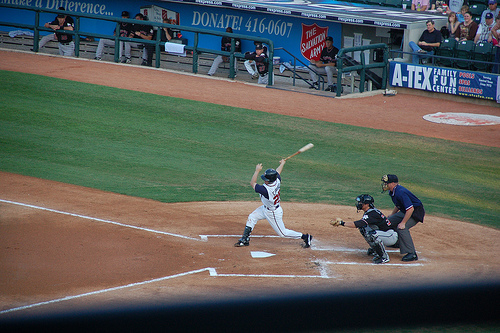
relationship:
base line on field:
[2, 195, 195, 248] [3, 43, 499, 316]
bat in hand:
[279, 140, 312, 161] [281, 161, 288, 165]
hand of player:
[281, 161, 288, 165] [242, 159, 312, 256]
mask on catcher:
[354, 195, 363, 214] [331, 192, 394, 265]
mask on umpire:
[381, 174, 391, 193] [383, 175, 432, 261]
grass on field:
[1, 71, 499, 231] [3, 43, 499, 316]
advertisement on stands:
[390, 63, 495, 99] [2, 1, 499, 114]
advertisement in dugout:
[1, 1, 344, 69] [0, 2, 392, 100]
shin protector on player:
[242, 218, 254, 241] [242, 159, 312, 256]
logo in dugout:
[299, 19, 333, 63] [0, 2, 392, 100]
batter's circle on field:
[422, 104, 499, 137] [3, 43, 499, 316]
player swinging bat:
[242, 159, 312, 256] [279, 140, 312, 161]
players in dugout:
[37, 9, 337, 86] [0, 2, 392, 100]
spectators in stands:
[399, 3, 497, 54] [2, 1, 499, 114]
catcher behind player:
[331, 192, 394, 265] [242, 159, 312, 256]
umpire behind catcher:
[383, 175, 432, 261] [331, 192, 394, 265]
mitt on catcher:
[328, 216, 342, 230] [331, 192, 394, 265]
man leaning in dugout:
[244, 40, 273, 78] [0, 2, 392, 100]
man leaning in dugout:
[46, 12, 80, 56] [0, 2, 392, 100]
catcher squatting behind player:
[331, 192, 394, 265] [242, 159, 312, 256]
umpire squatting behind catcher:
[383, 175, 432, 261] [331, 192, 394, 265]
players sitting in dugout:
[37, 9, 337, 86] [0, 2, 392, 100]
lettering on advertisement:
[188, 9, 291, 43] [1, 1, 344, 69]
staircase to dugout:
[270, 38, 359, 100] [0, 2, 392, 100]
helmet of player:
[259, 166, 276, 185] [242, 159, 312, 256]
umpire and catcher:
[383, 175, 432, 261] [331, 192, 394, 265]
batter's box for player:
[198, 212, 330, 278] [242, 159, 312, 256]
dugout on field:
[0, 2, 392, 100] [3, 43, 499, 316]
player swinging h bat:
[242, 159, 312, 256] [279, 140, 312, 161]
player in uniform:
[242, 159, 312, 256] [248, 184, 299, 240]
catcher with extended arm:
[331, 192, 394, 265] [330, 210, 366, 234]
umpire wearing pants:
[383, 175, 432, 261] [388, 215, 419, 254]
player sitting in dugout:
[242, 159, 312, 256] [0, 2, 392, 100]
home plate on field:
[251, 245, 272, 261] [3, 43, 499, 316]